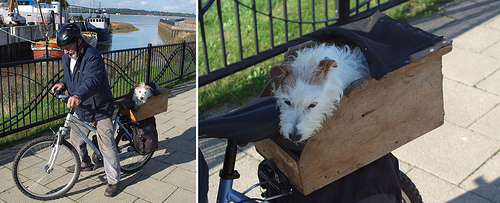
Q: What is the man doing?
A: Riding a bike.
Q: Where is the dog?
A: In a box.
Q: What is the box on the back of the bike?
A: A seat for the dog.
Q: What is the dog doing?
A: Looking down.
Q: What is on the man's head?
A: A hat.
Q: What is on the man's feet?
A: Sneakers.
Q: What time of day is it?
A: The daytime.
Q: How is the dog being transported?
A: On a bicycle.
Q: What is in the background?
A: The ocean.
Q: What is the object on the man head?
A: A helmet.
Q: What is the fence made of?
A: Iron.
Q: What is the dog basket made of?
A: Wood.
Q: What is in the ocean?
A: A boat.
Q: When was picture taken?
A: During daylight.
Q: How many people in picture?
A: One.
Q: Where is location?
A: By a river.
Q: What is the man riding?
A: A bike.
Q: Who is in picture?
A: A man.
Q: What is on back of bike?
A: A box.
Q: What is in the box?
A: A dog.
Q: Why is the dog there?
A: Going for a ride.